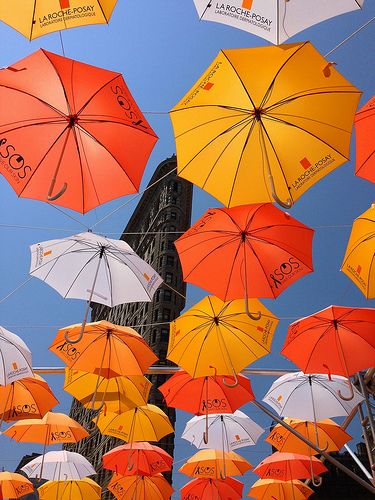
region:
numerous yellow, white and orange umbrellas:
[25, 144, 353, 489]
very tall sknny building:
[66, 189, 203, 498]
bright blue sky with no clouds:
[132, 13, 190, 66]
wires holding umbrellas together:
[66, 170, 210, 243]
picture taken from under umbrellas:
[24, 6, 372, 483]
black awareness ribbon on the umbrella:
[268, 268, 283, 298]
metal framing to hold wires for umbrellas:
[268, 363, 369, 486]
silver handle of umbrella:
[64, 318, 94, 353]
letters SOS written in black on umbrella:
[270, 252, 306, 285]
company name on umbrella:
[26, 0, 98, 38]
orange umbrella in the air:
[1, 48, 157, 211]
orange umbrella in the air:
[174, 205, 314, 300]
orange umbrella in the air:
[280, 305, 373, 377]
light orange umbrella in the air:
[55, 322, 155, 381]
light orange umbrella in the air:
[5, 409, 88, 445]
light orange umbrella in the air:
[183, 448, 248, 479]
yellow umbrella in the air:
[164, 41, 359, 206]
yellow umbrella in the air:
[168, 293, 276, 374]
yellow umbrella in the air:
[94, 404, 174, 443]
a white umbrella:
[30, 230, 163, 306]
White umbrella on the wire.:
[261, 369, 357, 424]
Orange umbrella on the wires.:
[279, 303, 373, 379]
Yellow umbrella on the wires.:
[166, 295, 275, 379]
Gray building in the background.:
[61, 231, 186, 498]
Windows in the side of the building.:
[126, 303, 145, 323]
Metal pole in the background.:
[1, 365, 372, 380]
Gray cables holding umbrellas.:
[1, 277, 47, 334]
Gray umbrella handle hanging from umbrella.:
[241, 293, 264, 323]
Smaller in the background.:
[269, 433, 374, 497]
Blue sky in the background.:
[297, 283, 334, 305]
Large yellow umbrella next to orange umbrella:
[165, 39, 361, 207]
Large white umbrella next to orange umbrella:
[24, 231, 162, 346]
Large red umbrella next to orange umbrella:
[101, 443, 172, 478]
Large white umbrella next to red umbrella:
[18, 448, 103, 498]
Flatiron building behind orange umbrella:
[57, 155, 192, 497]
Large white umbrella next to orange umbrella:
[181, 408, 262, 483]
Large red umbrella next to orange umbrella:
[251, 451, 328, 498]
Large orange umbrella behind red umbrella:
[245, 475, 313, 498]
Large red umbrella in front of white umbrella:
[0, 47, 158, 235]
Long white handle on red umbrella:
[45, 121, 72, 200]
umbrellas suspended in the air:
[6, 2, 368, 492]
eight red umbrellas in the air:
[1, 38, 374, 498]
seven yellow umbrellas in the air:
[4, 3, 374, 497]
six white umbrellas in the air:
[8, 3, 359, 498]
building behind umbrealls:
[66, 156, 180, 499]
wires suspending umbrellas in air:
[19, 39, 362, 489]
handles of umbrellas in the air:
[21, 87, 343, 489]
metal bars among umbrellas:
[20, 348, 371, 487]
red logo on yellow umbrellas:
[201, 79, 212, 94]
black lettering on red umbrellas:
[261, 251, 301, 285]